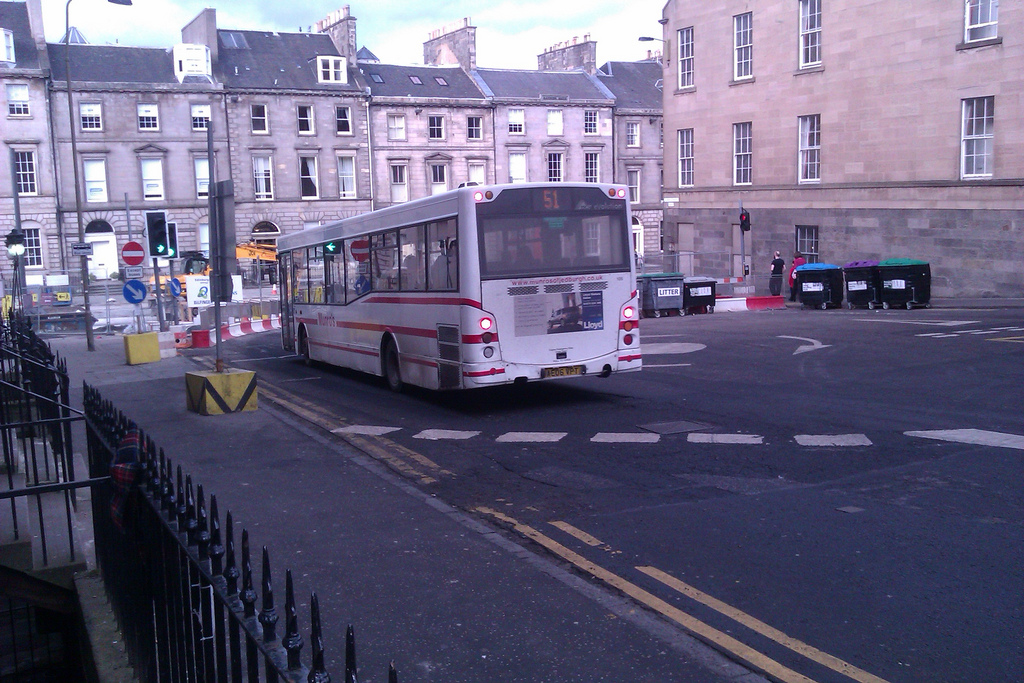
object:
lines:
[494, 492, 897, 681]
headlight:
[615, 304, 640, 322]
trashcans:
[792, 264, 844, 312]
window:
[422, 215, 462, 295]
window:
[475, 207, 630, 279]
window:
[318, 237, 347, 309]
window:
[3, 80, 35, 121]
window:
[74, 100, 107, 136]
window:
[726, 119, 755, 187]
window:
[953, 96, 1001, 187]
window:
[956, 0, 1001, 53]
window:
[729, 12, 756, 86]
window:
[792, 115, 827, 191]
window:
[670, 125, 698, 188]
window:
[794, 2, 826, 71]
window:
[506, 105, 526, 138]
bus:
[275, 178, 651, 401]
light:
[477, 317, 494, 332]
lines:
[462, 502, 823, 681]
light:
[150, 241, 169, 257]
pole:
[122, 191, 144, 334]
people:
[766, 250, 787, 297]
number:
[539, 189, 563, 209]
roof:
[0, 0, 666, 111]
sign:
[117, 240, 146, 267]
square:
[324, 421, 406, 439]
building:
[659, 0, 1023, 314]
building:
[0, 0, 663, 308]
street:
[0, 297, 1022, 681]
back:
[461, 181, 648, 391]